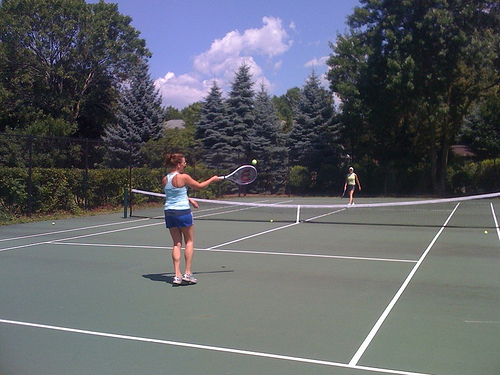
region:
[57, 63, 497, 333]
a couple of girls on a court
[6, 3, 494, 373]
a scene during the day time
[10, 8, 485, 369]
a scene outside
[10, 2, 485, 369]
a green tennis court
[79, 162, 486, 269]
a white and black net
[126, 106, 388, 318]
two people playing tennis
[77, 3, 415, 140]
a sky with some clouds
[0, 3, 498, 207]
a row of green trees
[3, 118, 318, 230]
a black fence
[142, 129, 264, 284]
a girl holding a racket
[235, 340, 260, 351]
Man swimming in the water on top of board.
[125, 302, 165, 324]
Man swimming in the water on top of board.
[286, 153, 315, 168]
Man swimming in the water on top of board.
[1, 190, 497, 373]
green covered tennis court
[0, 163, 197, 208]
row of trimmed hedges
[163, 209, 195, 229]
woman wears navy blue shorts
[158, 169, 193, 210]
an aqua colored tank top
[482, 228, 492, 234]
tennis ball lies on the court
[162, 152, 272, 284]
serving the tennis ball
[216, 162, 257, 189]
a tennis racquet by Wilson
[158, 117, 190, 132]
shingled roof of building behind trees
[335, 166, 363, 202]
a woman walks forward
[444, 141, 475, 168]
a brown building in the trees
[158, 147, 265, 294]
A person playing tennis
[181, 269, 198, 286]
The righ foot of the person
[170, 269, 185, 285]
The left foot of the person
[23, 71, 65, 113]
Part of the green trees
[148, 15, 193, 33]
Part of the sky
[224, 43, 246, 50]
Part of the cloud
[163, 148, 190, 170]
The head of the person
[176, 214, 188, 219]
Part of the blue short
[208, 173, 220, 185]
The right hand of the person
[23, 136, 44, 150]
Part of the fence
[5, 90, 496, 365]
The people are on a tennis court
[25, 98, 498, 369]
The people are playing a tennis game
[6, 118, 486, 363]
The people are getting some exercise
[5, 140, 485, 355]
The people are enjoying good recreation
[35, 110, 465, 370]
The people are wearing short pants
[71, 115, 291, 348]
The person is holding a tennis racket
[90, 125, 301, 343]
The person is hitting a tennis ball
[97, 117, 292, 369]
The person is casting a shadow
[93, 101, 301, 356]
The person is having a good time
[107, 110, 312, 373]
The person is enjoying the day